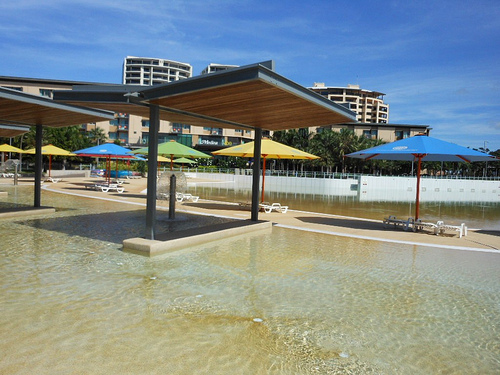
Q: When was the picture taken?
A: Daytime.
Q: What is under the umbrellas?
A: Bench.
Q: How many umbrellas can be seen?
A: Nine.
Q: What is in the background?
A: Buildings.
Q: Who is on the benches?
A: No one.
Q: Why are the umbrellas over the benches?
A: For shade.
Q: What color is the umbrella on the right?
A: Blue.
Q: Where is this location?
A: Pool.